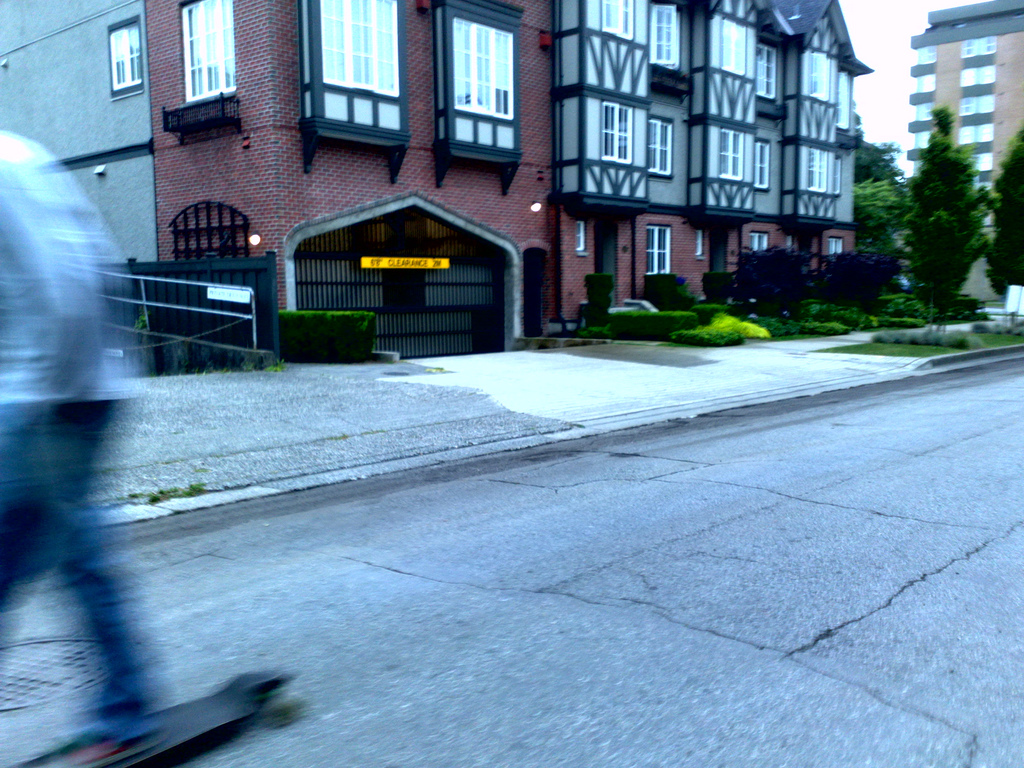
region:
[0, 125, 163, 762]
boy is riding skateboard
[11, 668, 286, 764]
skateboard is in motion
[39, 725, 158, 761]
shoe is red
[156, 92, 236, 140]
balcony is outside of window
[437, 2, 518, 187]
window is apart of building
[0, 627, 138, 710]
man hole cover is in street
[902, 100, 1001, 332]
tree is in front of building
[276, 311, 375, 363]
bush is beside garage door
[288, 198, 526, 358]
garage door is black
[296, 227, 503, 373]
Black garage door on a building.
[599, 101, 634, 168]
Window on a building.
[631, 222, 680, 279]
White frame around a window.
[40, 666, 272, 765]
Skateboard on a road.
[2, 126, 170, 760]
A person riding a skateboard.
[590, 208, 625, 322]
Doorway to a building.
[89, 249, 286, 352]
Black fence by a building.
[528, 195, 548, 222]
light on the building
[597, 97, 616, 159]
glass window on building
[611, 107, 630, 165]
glass window on building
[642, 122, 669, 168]
glass window on building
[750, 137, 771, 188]
glass window on building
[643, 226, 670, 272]
glass window on building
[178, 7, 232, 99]
glass window on building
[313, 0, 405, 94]
glass window on building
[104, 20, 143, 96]
glass window on building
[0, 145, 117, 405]
the arm of a guy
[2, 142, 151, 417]
the shirt of a guy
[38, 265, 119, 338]
the elbow of a guy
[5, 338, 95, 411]
the hand of a guy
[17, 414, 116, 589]
the left leg of a guy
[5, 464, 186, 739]
the right leg of a guy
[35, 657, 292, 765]
the skateboard of a guy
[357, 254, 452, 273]
Bright yellow rectangle sign.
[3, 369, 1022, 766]
A grey paved cracked road.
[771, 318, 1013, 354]
A grey sidewalk in front of a red building.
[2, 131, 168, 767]
A blurry person on the street.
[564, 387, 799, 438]
a concrete curb next to a street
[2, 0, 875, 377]
brick building with many windows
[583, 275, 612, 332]
green hedge growing in front of brick building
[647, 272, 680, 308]
green hedge growing in front of brick building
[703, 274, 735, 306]
green hedge growing in front of brick building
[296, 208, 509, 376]
garage area enclosed with black, metal fencing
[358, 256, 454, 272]
yellow clearance sign affixed to black, metal fencing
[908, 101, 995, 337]
full, green tree growing in front of brick building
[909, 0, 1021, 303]
tall, brick building sitting in background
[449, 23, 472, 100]
A window on a building.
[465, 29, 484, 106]
A window on a building.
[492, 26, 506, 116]
A window on a building.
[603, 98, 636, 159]
A window on a building.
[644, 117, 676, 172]
A window on a building.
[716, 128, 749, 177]
A window on a building.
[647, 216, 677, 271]
A window on a building.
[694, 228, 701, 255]
A window on a building.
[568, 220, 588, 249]
A window on a building.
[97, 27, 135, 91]
A window on a building.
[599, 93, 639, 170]
A window on a building.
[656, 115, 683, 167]
A window on a building.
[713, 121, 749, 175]
A window on a building.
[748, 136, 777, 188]
A window on a building.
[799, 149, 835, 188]
A window on a building.